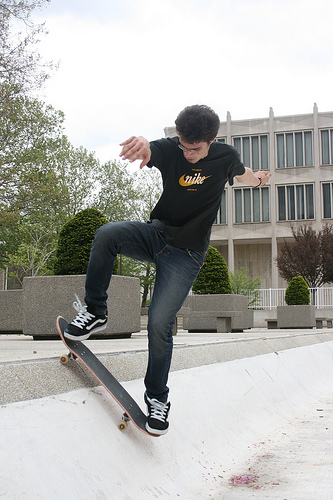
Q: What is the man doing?
A: Skateboarding.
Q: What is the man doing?
A: Skateboard trick.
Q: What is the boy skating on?
A: Skateboard.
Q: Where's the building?
A: Background.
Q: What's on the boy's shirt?
A: Nike.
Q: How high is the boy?
A: Not high.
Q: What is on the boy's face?
A: Glasses.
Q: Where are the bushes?
A: Behind the boy.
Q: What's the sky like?
A: Overcast.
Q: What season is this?
A: Summer.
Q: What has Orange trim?
A: Black skateboard.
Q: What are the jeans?
A: Blue.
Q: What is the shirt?
A: T Shirt.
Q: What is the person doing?
A: Skateboarding.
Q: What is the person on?
A: Skateboard.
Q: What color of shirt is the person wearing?
A: Black.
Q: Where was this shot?
A: Drained fountain.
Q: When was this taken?
A: Daytime.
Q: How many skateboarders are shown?
A: 1.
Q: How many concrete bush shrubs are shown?
A: 3.